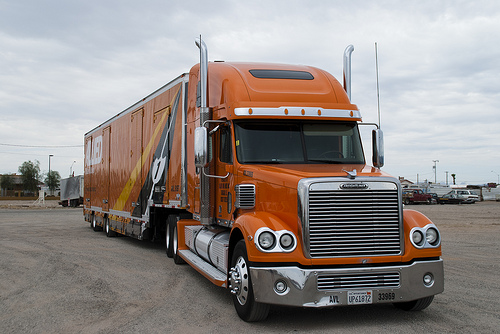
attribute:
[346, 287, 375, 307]
license plate — white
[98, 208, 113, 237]
wheel — black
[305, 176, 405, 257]
grill — chrome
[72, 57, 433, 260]
truck — black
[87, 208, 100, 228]
wheel — black 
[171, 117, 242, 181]
mirror — chrome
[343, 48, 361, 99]
exhaust pipe — chrome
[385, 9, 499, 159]
clouds — white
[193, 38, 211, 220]
exhaust pipe — chrome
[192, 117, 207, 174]
chrome mirror — truck's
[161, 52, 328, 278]
truck — orange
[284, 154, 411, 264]
grill — chrome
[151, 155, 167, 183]
sign — route one, white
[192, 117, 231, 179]
mirror — chrome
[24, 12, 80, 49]
clouds — white